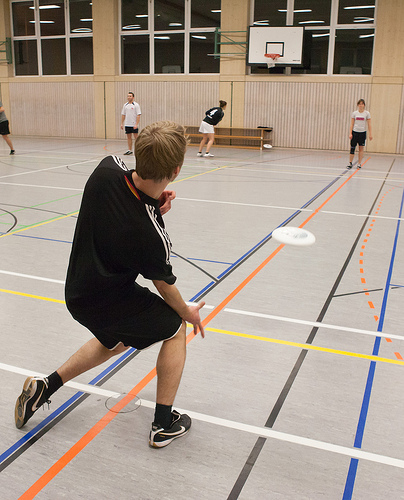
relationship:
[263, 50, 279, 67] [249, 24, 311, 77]
hoop for basketball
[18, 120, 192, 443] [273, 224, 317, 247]
guy playing frisbee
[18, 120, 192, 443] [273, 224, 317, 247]
guy catches frisbee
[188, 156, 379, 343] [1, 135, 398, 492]
line on court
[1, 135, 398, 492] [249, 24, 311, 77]
court for basketball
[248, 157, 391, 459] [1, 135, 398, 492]
line on court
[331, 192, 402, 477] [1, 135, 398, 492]
line on court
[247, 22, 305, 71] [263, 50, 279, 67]
backboard for hoop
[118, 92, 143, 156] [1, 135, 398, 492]
man on court